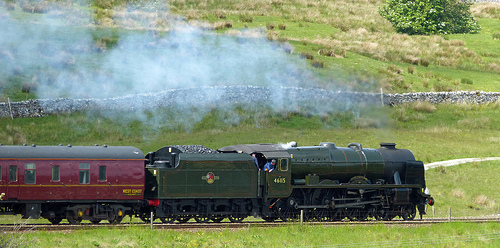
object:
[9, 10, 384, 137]
smoke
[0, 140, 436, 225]
train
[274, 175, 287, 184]
numbers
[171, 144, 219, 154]
coal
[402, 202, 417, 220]
wheels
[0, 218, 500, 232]
tracks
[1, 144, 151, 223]
train car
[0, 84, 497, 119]
wall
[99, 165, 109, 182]
window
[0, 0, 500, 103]
grass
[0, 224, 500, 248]
grass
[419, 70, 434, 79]
grass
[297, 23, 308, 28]
grass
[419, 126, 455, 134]
grass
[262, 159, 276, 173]
engineer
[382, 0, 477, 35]
bush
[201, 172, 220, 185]
logo